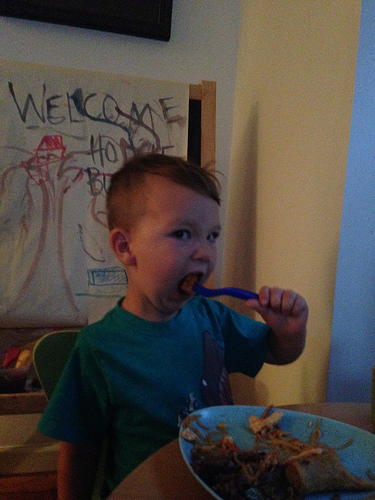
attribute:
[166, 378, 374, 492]
bowl — circular 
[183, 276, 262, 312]
tooth brush — blue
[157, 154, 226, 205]
hair — short hair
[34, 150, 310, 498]
baby — sitting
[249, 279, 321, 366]
arm — toddler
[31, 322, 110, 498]
chair — green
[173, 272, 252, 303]
toothbrush — blue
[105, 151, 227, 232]
hair cut — short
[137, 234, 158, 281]
skin — his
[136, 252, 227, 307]
mouth — baby's mouth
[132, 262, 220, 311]
mouth — baby's mouth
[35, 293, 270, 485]
shirt — blue